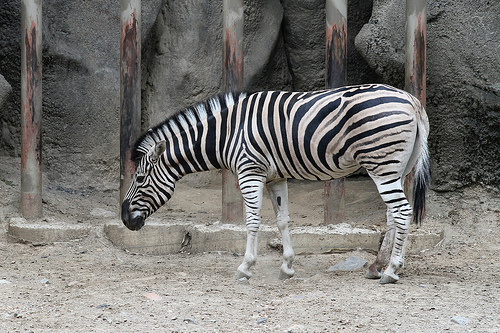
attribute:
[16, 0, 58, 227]
rail — round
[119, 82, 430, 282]
zebra — looking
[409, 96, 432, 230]
tail — black, white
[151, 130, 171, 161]
left — ear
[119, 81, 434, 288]
stripes — black and white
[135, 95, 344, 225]
zebra — left front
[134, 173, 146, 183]
eye — black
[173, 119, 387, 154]
stripes — horizontal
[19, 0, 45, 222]
bars — metal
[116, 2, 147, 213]
bars — metal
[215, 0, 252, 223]
bars — metal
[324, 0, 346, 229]
bars — metal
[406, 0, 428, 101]
bars — metal